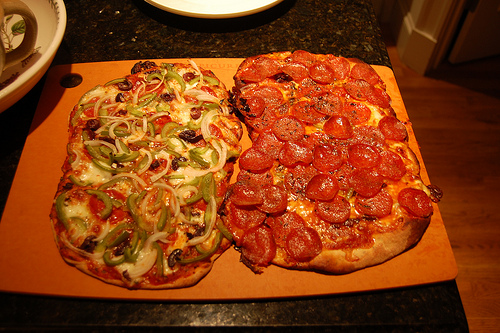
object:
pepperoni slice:
[284, 225, 322, 263]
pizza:
[213, 50, 444, 275]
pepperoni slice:
[399, 187, 434, 218]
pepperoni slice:
[306, 173, 341, 201]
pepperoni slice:
[323, 114, 355, 140]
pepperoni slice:
[378, 115, 408, 143]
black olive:
[86, 118, 99, 130]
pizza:
[47, 59, 244, 290]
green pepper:
[165, 71, 187, 95]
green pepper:
[95, 184, 115, 218]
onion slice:
[200, 108, 221, 142]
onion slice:
[164, 175, 180, 224]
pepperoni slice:
[309, 62, 335, 85]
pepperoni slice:
[350, 61, 380, 86]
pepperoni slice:
[236, 95, 266, 118]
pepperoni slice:
[239, 224, 275, 266]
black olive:
[131, 61, 144, 74]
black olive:
[168, 250, 183, 267]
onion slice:
[109, 174, 147, 188]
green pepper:
[55, 187, 72, 231]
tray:
[12, 80, 460, 302]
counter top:
[0, 251, 453, 331]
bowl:
[0, 0, 67, 114]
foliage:
[12, 19, 26, 37]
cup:
[1, 1, 39, 71]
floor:
[422, 19, 499, 333]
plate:
[143, 0, 285, 19]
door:
[446, 1, 500, 68]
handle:
[4, 54, 43, 84]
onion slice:
[109, 120, 122, 140]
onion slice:
[188, 56, 204, 88]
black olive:
[80, 234, 97, 252]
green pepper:
[202, 171, 213, 203]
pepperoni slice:
[257, 186, 289, 214]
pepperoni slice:
[271, 115, 306, 143]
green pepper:
[125, 194, 151, 234]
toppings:
[89, 81, 198, 254]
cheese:
[362, 100, 382, 128]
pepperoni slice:
[343, 102, 371, 124]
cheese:
[271, 139, 430, 249]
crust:
[292, 225, 440, 272]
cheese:
[66, 201, 125, 269]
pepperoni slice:
[241, 56, 280, 83]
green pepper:
[125, 98, 143, 119]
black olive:
[178, 128, 196, 139]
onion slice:
[210, 138, 228, 172]